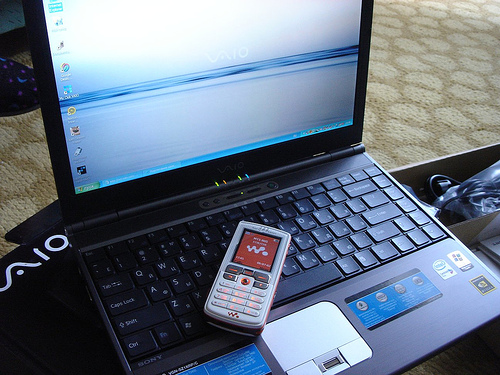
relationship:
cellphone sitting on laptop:
[201, 218, 294, 338] [38, 8, 479, 360]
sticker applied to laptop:
[366, 262, 433, 323] [38, 8, 479, 360]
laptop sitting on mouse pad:
[38, 8, 479, 360] [264, 291, 369, 373]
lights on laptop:
[198, 163, 259, 190] [38, 8, 479, 360]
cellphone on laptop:
[203, 220, 291, 337] [38, 8, 479, 360]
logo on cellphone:
[233, 227, 282, 272] [203, 220, 291, 337]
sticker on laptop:
[344, 268, 443, 332] [319, 225, 467, 366]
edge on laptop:
[356, 0, 377, 125] [38, 8, 479, 360]